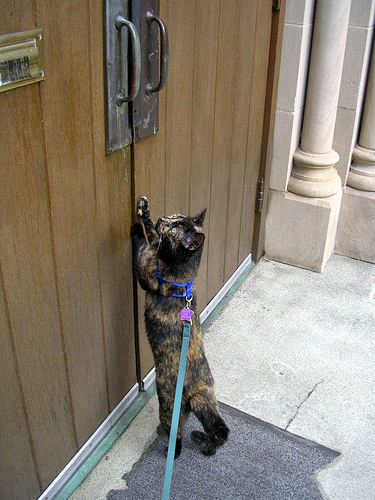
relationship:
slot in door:
[1, 23, 46, 93] [1, 1, 288, 499]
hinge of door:
[254, 178, 266, 216] [1, 1, 288, 499]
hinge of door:
[269, 1, 284, 13] [1, 1, 288, 499]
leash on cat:
[158, 320, 192, 500] [130, 196, 230, 458]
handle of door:
[143, 10, 169, 100] [1, 1, 288, 499]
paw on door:
[137, 194, 150, 216] [1, 1, 288, 499]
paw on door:
[130, 218, 143, 239] [1, 1, 288, 499]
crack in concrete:
[283, 376, 324, 428] [64, 253, 374, 500]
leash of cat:
[158, 320, 192, 500] [130, 196, 230, 458]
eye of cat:
[170, 225, 180, 235] [130, 196, 230, 458]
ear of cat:
[189, 230, 206, 251] [130, 196, 230, 458]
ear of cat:
[197, 207, 209, 225] [130, 196, 230, 458]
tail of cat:
[189, 392, 230, 457] [130, 196, 230, 458]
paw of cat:
[137, 194, 150, 216] [130, 196, 230, 458]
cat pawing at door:
[130, 196, 230, 458] [1, 1, 288, 499]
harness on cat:
[154, 273, 192, 298] [130, 196, 230, 458]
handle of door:
[117, 17, 142, 107] [1, 1, 288, 499]